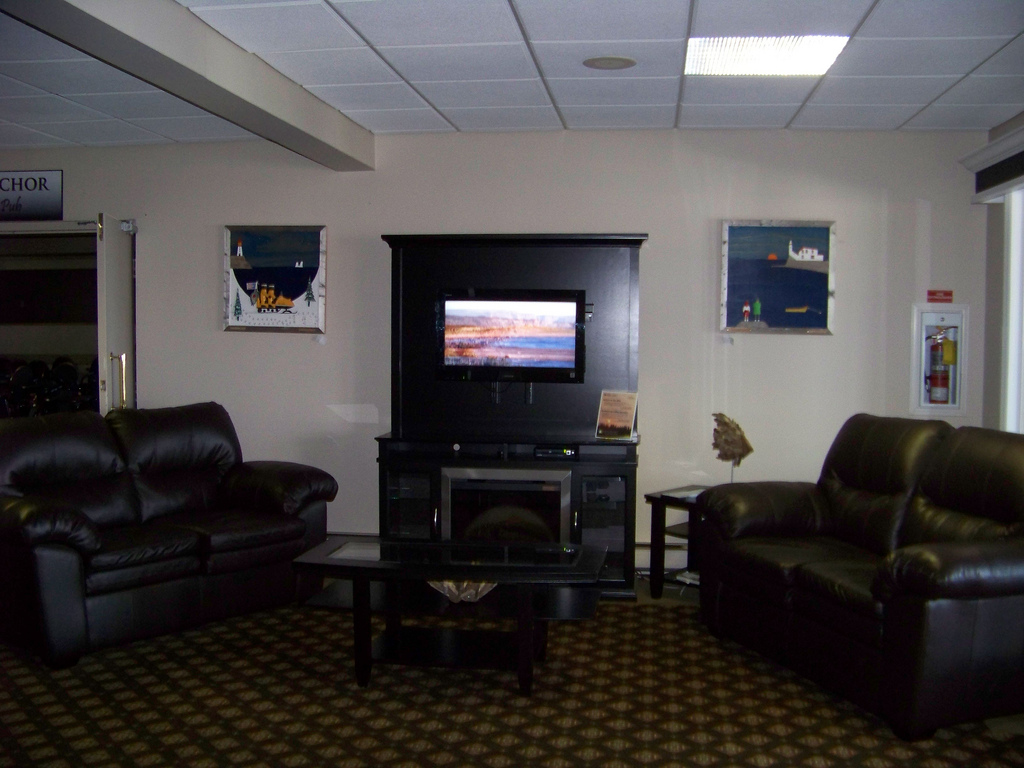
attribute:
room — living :
[18, 28, 991, 742]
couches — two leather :
[98, 369, 973, 648]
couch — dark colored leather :
[716, 413, 991, 675]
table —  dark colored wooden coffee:
[353, 497, 673, 668]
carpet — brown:
[320, 590, 787, 763]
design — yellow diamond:
[530, 717, 589, 750]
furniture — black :
[647, 476, 725, 591]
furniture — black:
[358, 225, 657, 599]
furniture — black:
[21, 381, 326, 641]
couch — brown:
[631, 299, 967, 740]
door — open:
[13, 220, 147, 417]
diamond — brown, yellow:
[102, 663, 224, 752]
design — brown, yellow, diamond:
[334, 717, 363, 743]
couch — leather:
[672, 406, 1022, 741]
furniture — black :
[670, 392, 1021, 710]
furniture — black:
[700, 418, 986, 665]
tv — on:
[420, 282, 589, 388]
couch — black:
[1, 398, 339, 664]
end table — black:
[642, 480, 714, 597]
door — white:
[93, 208, 135, 416]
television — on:
[430, 284, 588, 388]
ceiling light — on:
[683, 33, 852, 79]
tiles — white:
[346, 7, 560, 120]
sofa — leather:
[669, 394, 1020, 729]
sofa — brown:
[681, 405, 1023, 714]